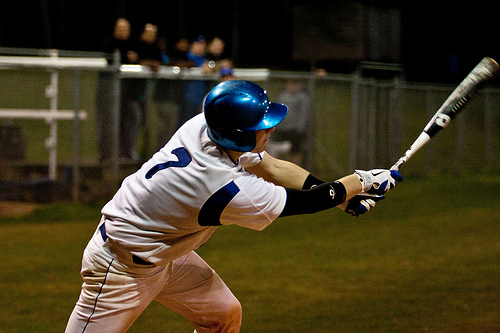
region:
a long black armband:
[278, 179, 346, 216]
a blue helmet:
[202, 75, 285, 152]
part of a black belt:
[130, 253, 160, 263]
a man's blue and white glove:
[355, 164, 399, 192]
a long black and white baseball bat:
[355, 55, 497, 214]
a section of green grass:
[291, 228, 492, 332]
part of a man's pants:
[61, 232, 248, 332]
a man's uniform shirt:
[102, 110, 290, 256]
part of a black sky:
[248, 5, 377, 51]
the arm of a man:
[254, 150, 306, 186]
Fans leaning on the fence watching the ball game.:
[107, 18, 227, 66]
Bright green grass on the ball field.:
[374, 210, 462, 305]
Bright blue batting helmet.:
[198, 76, 292, 153]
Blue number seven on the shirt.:
[138, 131, 199, 202]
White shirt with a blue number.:
[106, 105, 209, 273]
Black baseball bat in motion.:
[380, 53, 496, 194]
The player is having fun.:
[82, 60, 302, 325]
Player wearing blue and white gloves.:
[339, 155, 410, 219]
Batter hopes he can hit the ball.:
[140, 55, 336, 205]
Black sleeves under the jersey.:
[280, 175, 347, 232]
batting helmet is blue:
[198, 65, 307, 164]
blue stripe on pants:
[75, 242, 117, 328]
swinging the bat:
[335, 40, 488, 227]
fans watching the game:
[100, 11, 280, 89]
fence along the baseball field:
[92, 32, 493, 187]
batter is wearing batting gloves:
[353, 152, 403, 232]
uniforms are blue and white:
[55, 97, 293, 329]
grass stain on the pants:
[85, 238, 115, 295]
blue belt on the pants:
[67, 190, 193, 291]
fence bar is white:
[0, 57, 270, 86]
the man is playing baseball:
[32, 52, 481, 280]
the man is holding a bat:
[335, 36, 498, 261]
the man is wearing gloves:
[322, 137, 419, 234]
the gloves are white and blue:
[330, 142, 428, 245]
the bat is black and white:
[360, 29, 485, 200]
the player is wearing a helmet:
[177, 64, 303, 173]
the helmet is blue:
[195, 62, 312, 169]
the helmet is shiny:
[188, 61, 309, 161]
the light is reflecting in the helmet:
[239, 77, 289, 144]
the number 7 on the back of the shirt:
[119, 111, 202, 219]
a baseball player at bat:
[34, 19, 494, 286]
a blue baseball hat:
[189, 59, 311, 156]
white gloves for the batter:
[340, 153, 414, 228]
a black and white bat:
[349, 39, 499, 252]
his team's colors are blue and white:
[118, 122, 250, 272]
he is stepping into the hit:
[107, 21, 498, 225]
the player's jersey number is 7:
[91, 130, 219, 208]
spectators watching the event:
[46, 13, 275, 93]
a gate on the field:
[12, 45, 175, 195]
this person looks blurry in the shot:
[262, 71, 347, 171]